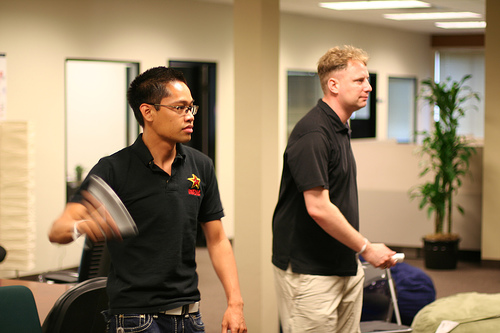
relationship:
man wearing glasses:
[44, 61, 254, 330] [144, 97, 201, 122]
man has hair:
[44, 61, 254, 330] [122, 65, 188, 130]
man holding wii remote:
[44, 61, 254, 330] [82, 166, 143, 240]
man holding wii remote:
[266, 39, 407, 332] [378, 243, 409, 272]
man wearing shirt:
[44, 61, 254, 330] [68, 131, 227, 323]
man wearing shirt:
[266, 39, 407, 332] [267, 97, 363, 279]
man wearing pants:
[266, 39, 407, 332] [270, 255, 368, 332]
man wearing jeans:
[44, 61, 254, 330] [95, 300, 208, 333]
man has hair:
[266, 39, 407, 332] [314, 42, 370, 99]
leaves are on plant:
[408, 72, 487, 217] [411, 72, 485, 274]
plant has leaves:
[411, 72, 485, 274] [408, 72, 487, 217]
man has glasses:
[44, 61, 254, 330] [144, 97, 201, 122]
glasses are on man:
[144, 97, 201, 122] [44, 61, 254, 330]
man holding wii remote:
[266, 39, 407, 332] [82, 166, 143, 240]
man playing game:
[44, 61, 254, 330] [81, 169, 145, 244]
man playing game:
[266, 39, 407, 332] [374, 242, 409, 275]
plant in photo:
[411, 72, 485, 274] [1, 2, 496, 332]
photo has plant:
[1, 2, 496, 332] [411, 72, 485, 274]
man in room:
[44, 61, 254, 330] [1, 1, 496, 331]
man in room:
[266, 39, 407, 332] [1, 1, 496, 331]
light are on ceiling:
[317, 0, 432, 11] [280, 0, 485, 54]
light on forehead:
[169, 80, 186, 95] [160, 77, 194, 105]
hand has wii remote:
[75, 189, 123, 246] [82, 166, 143, 240]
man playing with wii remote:
[44, 61, 254, 330] [82, 166, 143, 240]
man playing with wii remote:
[266, 39, 407, 332] [378, 243, 409, 272]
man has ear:
[266, 39, 407, 332] [323, 76, 342, 99]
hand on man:
[75, 189, 123, 246] [44, 61, 254, 330]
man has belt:
[44, 61, 254, 330] [159, 296, 204, 318]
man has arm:
[266, 39, 407, 332] [286, 136, 370, 268]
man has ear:
[44, 61, 254, 330] [134, 99, 156, 126]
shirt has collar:
[68, 131, 227, 323] [129, 132, 187, 175]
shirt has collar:
[267, 97, 363, 279] [313, 98, 353, 139]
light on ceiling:
[312, 0, 436, 14] [280, 0, 485, 54]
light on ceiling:
[382, 9, 486, 22] [280, 0, 485, 54]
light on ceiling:
[430, 19, 489, 34] [280, 0, 485, 54]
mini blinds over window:
[439, 57, 484, 141] [432, 48, 486, 147]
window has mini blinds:
[432, 48, 486, 147] [439, 57, 484, 141]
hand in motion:
[75, 189, 123, 246] [73, 187, 122, 248]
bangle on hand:
[68, 219, 84, 246] [75, 189, 123, 246]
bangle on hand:
[355, 235, 372, 259] [358, 229, 400, 274]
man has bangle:
[44, 61, 254, 330] [68, 219, 84, 246]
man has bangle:
[266, 39, 407, 332] [355, 235, 372, 259]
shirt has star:
[68, 131, 227, 323] [185, 170, 205, 193]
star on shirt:
[185, 170, 205, 193] [68, 131, 227, 323]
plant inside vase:
[411, 72, 485, 274] [417, 233, 465, 273]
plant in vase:
[411, 72, 485, 274] [417, 233, 465, 273]